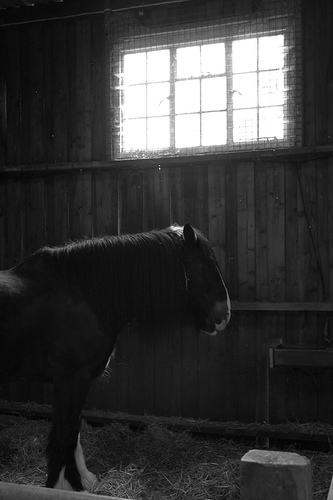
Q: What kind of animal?
A: Horse.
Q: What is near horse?
A: Stone.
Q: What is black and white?
A: The picture.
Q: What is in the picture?
A: A horse.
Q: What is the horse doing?
A: Standing.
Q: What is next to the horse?
A: A wall.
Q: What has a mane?
A: The horse.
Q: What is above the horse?
A: A window.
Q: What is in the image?
A: Horse.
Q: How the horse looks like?
A: Long mane and white nose.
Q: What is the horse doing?
A: Resting in its stall.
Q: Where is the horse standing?
A: Under a window.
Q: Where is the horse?
A: In barn.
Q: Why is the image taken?
A: Remembrance.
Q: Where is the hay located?
A: Horse stall.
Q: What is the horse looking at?
A: Food.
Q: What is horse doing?
A: Standing there.